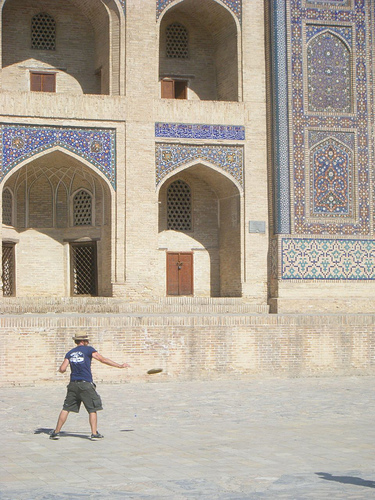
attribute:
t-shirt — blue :
[59, 346, 97, 381]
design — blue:
[293, 271, 299, 276]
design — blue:
[259, 226, 369, 288]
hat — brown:
[71, 330, 88, 340]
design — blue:
[279, 238, 374, 279]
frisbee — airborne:
[147, 367, 162, 374]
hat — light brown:
[71, 330, 91, 340]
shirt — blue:
[64, 345, 95, 378]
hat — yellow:
[73, 329, 89, 339]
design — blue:
[269, 0, 374, 280]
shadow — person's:
[311, 467, 373, 491]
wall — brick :
[192, 309, 233, 351]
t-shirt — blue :
[59, 341, 100, 384]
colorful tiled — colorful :
[281, 148, 351, 276]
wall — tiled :
[270, 2, 373, 273]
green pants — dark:
[61, 374, 104, 415]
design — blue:
[279, 231, 373, 279]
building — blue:
[1, 1, 372, 392]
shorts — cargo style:
[62, 378, 133, 417]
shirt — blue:
[63, 344, 96, 384]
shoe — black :
[85, 426, 106, 444]